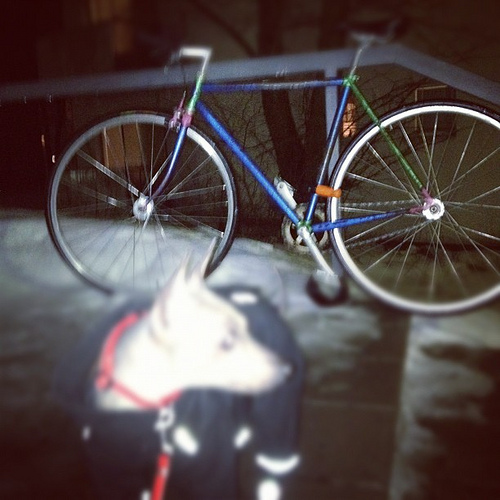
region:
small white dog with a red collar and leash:
[75, 236, 292, 497]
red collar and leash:
[97, 310, 175, 498]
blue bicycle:
[44, 17, 498, 311]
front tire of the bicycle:
[45, 107, 237, 294]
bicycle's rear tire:
[323, 100, 497, 312]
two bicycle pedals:
[273, 177, 346, 305]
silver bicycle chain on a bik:
[281, 200, 442, 250]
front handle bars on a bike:
[161, 45, 210, 63]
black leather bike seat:
[347, 16, 407, 46]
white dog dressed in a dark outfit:
[55, 240, 303, 498]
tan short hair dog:
[93, 255, 290, 420]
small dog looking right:
[78, 257, 315, 434]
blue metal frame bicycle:
[36, 22, 496, 334]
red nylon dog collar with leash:
[85, 309, 181, 499]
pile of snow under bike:
[7, 215, 292, 317]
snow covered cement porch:
[318, 305, 465, 498]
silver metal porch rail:
[50, 24, 498, 138]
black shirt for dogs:
[87, 294, 309, 499]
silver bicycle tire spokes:
[76, 153, 202, 258]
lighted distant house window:
[325, 87, 370, 163]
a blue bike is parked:
[36, 30, 496, 330]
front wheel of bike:
[41, 107, 239, 298]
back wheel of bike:
[319, 99, 496, 321]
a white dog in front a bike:
[53, 243, 334, 498]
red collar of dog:
[74, 314, 186, 484]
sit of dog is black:
[343, 16, 399, 70]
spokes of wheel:
[71, 136, 211, 273]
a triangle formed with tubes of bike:
[201, 69, 349, 239]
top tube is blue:
[207, 70, 350, 100]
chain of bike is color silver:
[276, 186, 447, 261]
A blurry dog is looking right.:
[57, 236, 303, 497]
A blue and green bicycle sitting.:
[45, 48, 496, 318]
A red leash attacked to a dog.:
[97, 298, 189, 498]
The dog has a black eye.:
[215, 326, 240, 352]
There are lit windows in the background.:
[62, 0, 161, 185]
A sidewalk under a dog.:
[4, 202, 499, 470]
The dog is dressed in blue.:
[62, 283, 299, 471]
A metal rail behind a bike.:
[0, 58, 495, 109]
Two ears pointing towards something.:
[171, 240, 222, 283]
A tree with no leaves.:
[193, 10, 494, 242]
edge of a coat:
[259, 331, 292, 379]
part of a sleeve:
[259, 415, 292, 457]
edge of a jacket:
[200, 366, 255, 406]